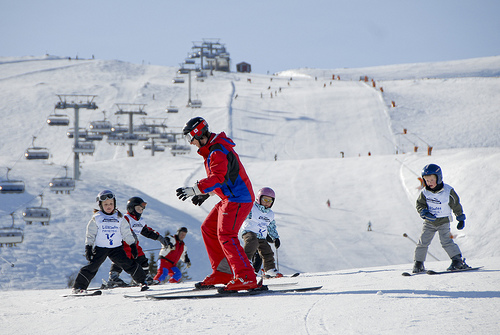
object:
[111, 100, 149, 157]
lift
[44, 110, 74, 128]
chair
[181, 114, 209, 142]
helmet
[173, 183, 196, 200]
glove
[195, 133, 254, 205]
coat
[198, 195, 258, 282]
pants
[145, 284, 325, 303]
ski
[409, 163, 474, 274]
child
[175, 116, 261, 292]
instructor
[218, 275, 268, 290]
boot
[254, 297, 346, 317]
snow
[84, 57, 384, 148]
mountain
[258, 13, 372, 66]
sky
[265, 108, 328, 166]
ground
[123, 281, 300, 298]
skis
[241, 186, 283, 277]
girl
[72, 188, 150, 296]
kids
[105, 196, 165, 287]
kid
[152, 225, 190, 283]
people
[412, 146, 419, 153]
barrels